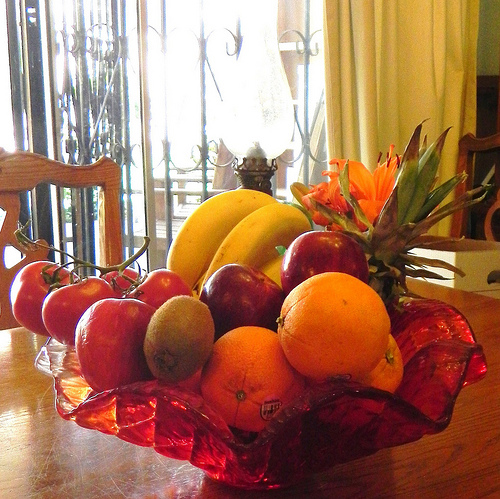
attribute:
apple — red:
[199, 260, 287, 340]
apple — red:
[199, 257, 282, 327]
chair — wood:
[3, 150, 123, 330]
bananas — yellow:
[148, 168, 318, 328]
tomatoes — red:
[6, 238, 190, 391]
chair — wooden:
[0, 142, 128, 332]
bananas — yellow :
[164, 187, 311, 297]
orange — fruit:
[267, 270, 398, 413]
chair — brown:
[0, 148, 131, 260]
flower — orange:
[329, 151, 398, 199]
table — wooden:
[75, 106, 499, 468]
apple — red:
[198, 265, 281, 323]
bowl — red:
[32, 293, 487, 490]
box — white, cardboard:
[394, 234, 497, 296]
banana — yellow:
[154, 179, 281, 276]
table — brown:
[3, 269, 498, 496]